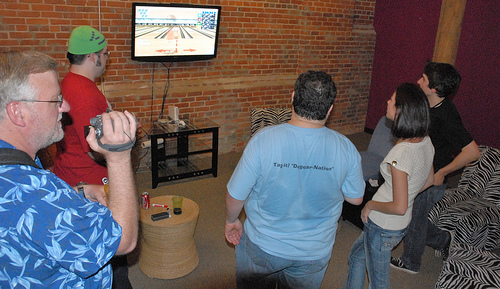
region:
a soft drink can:
[137, 190, 154, 215]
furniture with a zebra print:
[406, 141, 497, 288]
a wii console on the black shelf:
[155, 99, 190, 132]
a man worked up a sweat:
[228, 78, 365, 262]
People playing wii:
[230, 58, 455, 288]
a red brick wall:
[3, 1, 376, 156]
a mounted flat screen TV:
[133, 10, 219, 61]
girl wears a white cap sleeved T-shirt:
[367, 133, 435, 228]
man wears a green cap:
[67, 23, 109, 54]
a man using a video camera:
[1, 43, 176, 202]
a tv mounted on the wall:
[123, 0, 238, 106]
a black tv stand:
[123, 95, 236, 193]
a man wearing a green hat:
[68, 16, 110, 88]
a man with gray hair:
[5, 49, 83, 157]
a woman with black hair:
[381, 71, 441, 150]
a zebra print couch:
[435, 153, 499, 278]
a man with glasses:
[58, 34, 145, 90]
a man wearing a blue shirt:
[217, 43, 354, 279]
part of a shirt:
[290, 184, 297, 206]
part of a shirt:
[95, 198, 108, 219]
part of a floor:
[188, 223, 206, 244]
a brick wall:
[6, 0, 343, 127]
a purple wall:
[372, 8, 490, 153]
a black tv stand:
[150, 124, 223, 181]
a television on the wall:
[131, 2, 216, 59]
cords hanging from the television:
[148, 68, 175, 112]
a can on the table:
[138, 190, 150, 209]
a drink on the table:
[170, 196, 177, 213]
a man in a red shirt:
[58, 33, 98, 153]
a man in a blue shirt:
[238, 68, 333, 278]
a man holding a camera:
[9, 51, 131, 273]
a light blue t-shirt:
[225, 121, 365, 257]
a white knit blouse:
[368, 137, 434, 229]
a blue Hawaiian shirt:
[3, 164, 122, 286]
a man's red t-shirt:
[58, 72, 118, 187]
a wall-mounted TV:
[130, 0, 220, 61]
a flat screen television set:
[130, 2, 221, 62]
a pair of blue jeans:
[349, 216, 407, 283]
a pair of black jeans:
[403, 183, 452, 265]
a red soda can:
[140, 190, 150, 208]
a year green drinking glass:
[171, 195, 183, 212]